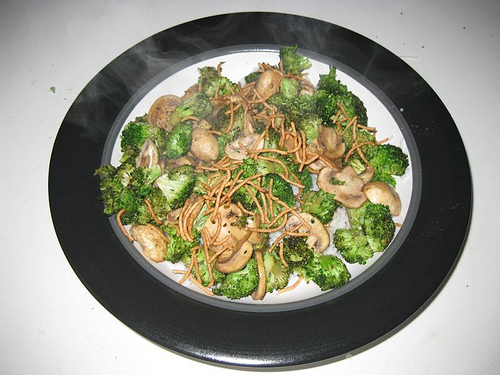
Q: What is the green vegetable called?
A: Broccoli.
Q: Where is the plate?
A: Table.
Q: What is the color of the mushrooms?
A: Brown.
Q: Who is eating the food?
A: No one.